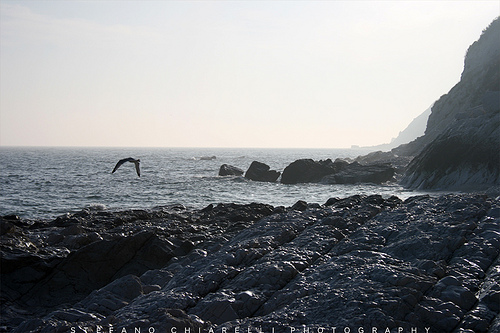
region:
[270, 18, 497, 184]
a large rock mountain.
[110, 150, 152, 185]
An arch in the ocean.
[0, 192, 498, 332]
a rocky beach.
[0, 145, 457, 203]
a body of water near rocks.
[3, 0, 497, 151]
a hazy pink sky.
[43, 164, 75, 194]
a section of choppy water.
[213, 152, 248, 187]
a rock in the ocean.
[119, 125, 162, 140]
a section of a pink sky.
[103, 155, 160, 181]
a strange rock formation.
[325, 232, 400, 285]
a section of rocky beach.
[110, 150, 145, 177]
seagull in flight over rocky beach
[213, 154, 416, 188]
outcrop of large boulders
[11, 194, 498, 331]
very rocky rough beach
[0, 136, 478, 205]
choppy looking sea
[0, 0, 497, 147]
grey overcast skies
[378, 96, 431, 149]
misty looking distant cliff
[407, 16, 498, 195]
high steep cliffs dropping off into the sea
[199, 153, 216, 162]
barely visible rock out farther in the sea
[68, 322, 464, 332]
name of the photography studio who took this shot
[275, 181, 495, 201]
small inlet formed by rocky coastline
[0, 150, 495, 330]
Rocks at the edge of the water.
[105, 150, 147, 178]
A bird flying over the water.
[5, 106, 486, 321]
A rocky shoreline.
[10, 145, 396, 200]
Choppy water.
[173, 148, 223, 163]
A wave in the water.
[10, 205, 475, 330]
Cravesses in the rock.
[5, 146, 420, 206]
Dark blue water.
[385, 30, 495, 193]
Mountains along the shore.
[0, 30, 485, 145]
A light blue sky.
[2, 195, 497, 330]
Crags in the rocks.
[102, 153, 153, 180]
A small black bird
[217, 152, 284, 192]
The two rocks to the side of the shore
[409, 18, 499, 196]
A side shore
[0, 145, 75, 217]
A portion of water to the left of the sea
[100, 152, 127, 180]
The left wing of the bird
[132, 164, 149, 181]
the right wing of the bird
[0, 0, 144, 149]
The top left portion of the sea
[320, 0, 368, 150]
The right portion of the sky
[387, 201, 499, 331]
The bottom right portion of the rocky shore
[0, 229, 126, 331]
The bottom left portion of the rocky shore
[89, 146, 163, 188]
Bird flying around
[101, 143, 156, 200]
This is a bird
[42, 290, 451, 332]
"Sepeano Chiare Photography"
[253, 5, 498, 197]
Mountains in the shot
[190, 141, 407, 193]
Rocks at the bottom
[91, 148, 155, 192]
Only bird in the shot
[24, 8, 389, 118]
It is sunny outside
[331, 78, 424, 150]
Another mountain to the side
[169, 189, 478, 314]
The rocks are black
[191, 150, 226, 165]
An object in the far back